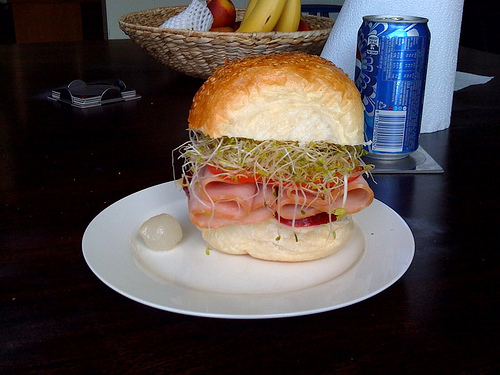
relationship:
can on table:
[350, 13, 430, 161] [4, 36, 494, 366]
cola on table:
[359, 15, 430, 162] [4, 36, 494, 366]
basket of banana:
[115, 22, 331, 77] [269, 0, 302, 32]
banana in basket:
[233, 0, 289, 36] [116, 5, 336, 79]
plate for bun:
[80, 175, 415, 317] [186, 51, 372, 145]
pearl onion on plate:
[134, 215, 183, 247] [80, 175, 415, 317]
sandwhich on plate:
[185, 51, 373, 261] [80, 175, 415, 317]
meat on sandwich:
[185, 170, 279, 229] [189, 52, 369, 259]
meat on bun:
[185, 170, 279, 229] [196, 55, 361, 140]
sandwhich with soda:
[170, 49, 377, 264] [351, 10, 439, 162]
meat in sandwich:
[182, 173, 374, 222] [189, 52, 369, 259]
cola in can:
[352, 13, 430, 163] [344, 5, 438, 174]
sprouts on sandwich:
[175, 134, 371, 197] [166, 47, 376, 265]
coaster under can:
[361, 140, 451, 181] [354, 14, 429, 159]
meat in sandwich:
[181, 164, 379, 227] [203, 60, 370, 257]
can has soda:
[344, 5, 438, 174] [334, 11, 441, 168]